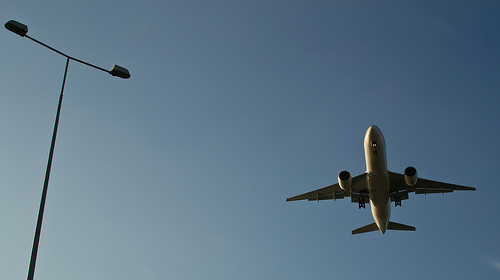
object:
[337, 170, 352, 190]
jet engine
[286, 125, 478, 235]
passenger jet